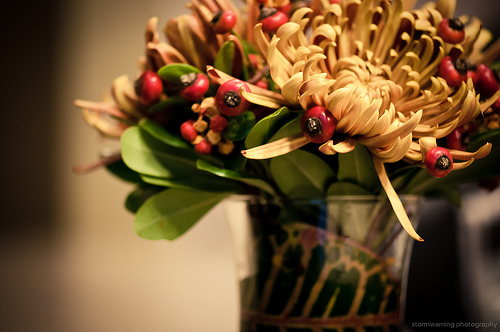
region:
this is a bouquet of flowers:
[57, 1, 493, 227]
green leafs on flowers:
[114, 114, 217, 216]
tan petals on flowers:
[270, 25, 317, 78]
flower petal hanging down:
[366, 145, 431, 244]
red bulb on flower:
[296, 101, 338, 146]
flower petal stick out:
[236, 114, 316, 176]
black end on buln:
[220, 88, 243, 108]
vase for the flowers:
[186, 140, 437, 330]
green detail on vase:
[242, 224, 399, 322]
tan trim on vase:
[266, 224, 402, 319]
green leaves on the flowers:
[131, 175, 216, 252]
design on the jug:
[283, 254, 403, 314]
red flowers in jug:
[171, 77, 265, 159]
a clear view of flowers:
[111, 0, 486, 282]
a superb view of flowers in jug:
[121, 23, 466, 327]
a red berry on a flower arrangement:
[301, 105, 336, 143]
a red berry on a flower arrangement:
[420, 140, 452, 178]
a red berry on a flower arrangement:
[446, 125, 467, 147]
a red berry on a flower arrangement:
[437, 50, 468, 89]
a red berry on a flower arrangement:
[476, 59, 498, 91]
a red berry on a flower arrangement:
[436, 14, 464, 47]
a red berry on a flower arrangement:
[256, 4, 289, 36]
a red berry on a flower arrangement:
[202, 9, 238, 37]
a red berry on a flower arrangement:
[131, 70, 163, 109]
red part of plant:
[213, 78, 249, 118]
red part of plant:
[136, 69, 164, 100]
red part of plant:
[178, 72, 213, 99]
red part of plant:
[210, 9, 235, 33]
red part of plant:
[424, 144, 451, 176]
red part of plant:
[443, 56, 466, 81]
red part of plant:
[438, 17, 463, 40]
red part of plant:
[478, 62, 499, 86]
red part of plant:
[461, 70, 478, 82]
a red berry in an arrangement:
[418, 143, 459, 178]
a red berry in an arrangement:
[297, 103, 337, 141]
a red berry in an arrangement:
[438, 51, 470, 96]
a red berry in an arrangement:
[476, 61, 496, 98]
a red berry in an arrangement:
[435, 13, 468, 44]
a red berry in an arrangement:
[249, 3, 291, 33]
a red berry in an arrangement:
[200, 8, 246, 32]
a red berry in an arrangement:
[130, 70, 162, 104]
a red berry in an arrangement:
[175, 70, 207, 100]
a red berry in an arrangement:
[213, 75, 247, 115]